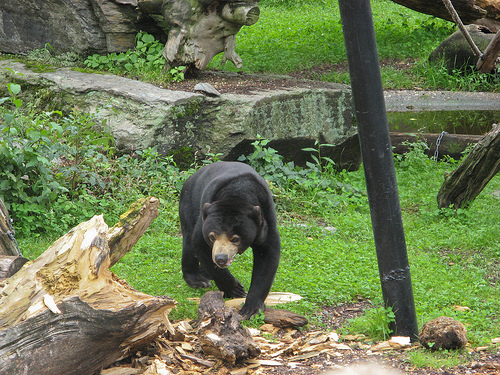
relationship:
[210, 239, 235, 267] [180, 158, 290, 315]
snout of bear cub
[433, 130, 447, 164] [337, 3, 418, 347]
chain behind pillar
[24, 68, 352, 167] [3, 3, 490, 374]
rock in enclosure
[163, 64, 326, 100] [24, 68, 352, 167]
soil on rock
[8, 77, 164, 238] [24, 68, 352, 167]
vegetation growing by rock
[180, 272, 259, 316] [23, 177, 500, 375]
paws on grass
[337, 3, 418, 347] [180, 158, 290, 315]
pillar to right of bear cub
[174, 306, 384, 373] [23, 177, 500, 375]
wood chips on grass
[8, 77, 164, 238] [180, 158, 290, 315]
vegetation behind bear cub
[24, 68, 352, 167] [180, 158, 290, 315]
rock behind bear cub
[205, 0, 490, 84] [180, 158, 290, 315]
grass behind bear cub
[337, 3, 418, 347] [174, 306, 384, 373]
pillar near wood chips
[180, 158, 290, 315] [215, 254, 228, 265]
bear cub has a nose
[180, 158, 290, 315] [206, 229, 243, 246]
bear cub has eyes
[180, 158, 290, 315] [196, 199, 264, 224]
bear cub has ears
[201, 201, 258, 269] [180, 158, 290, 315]
head of bear cub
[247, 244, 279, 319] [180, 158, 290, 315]
leg of bear cub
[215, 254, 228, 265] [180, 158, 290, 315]
nose of bear cub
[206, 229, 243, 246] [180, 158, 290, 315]
eyes of bear cub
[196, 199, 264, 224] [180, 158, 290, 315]
ears of bear cub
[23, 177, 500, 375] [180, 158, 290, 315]
grass beneath bear cub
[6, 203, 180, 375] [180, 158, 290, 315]
log next to bear cub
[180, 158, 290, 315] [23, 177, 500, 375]
bear cub on grass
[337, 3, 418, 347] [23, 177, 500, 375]
pillar sticking out of grass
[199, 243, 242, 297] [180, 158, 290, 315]
leg of bear cub